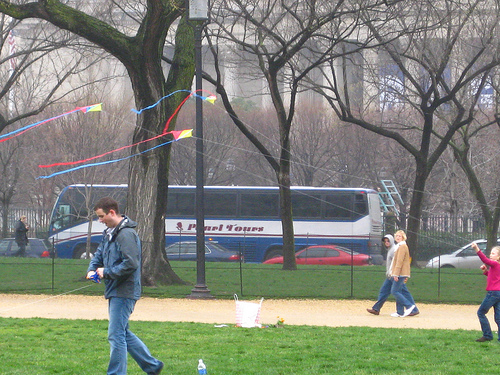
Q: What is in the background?
A: Bus.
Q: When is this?
A: Late afternoon.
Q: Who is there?
A: Passerbys.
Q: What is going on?
A: People walking.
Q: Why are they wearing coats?
A: Cool weather.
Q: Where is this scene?
A: Park.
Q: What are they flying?
A: Kites.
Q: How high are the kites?
A: Not high.